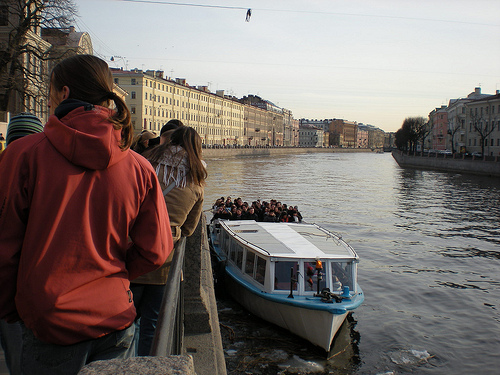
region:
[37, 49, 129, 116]
a person's head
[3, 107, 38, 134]
a person's head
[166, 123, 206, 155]
a person's head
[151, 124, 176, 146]
a person's head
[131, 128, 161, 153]
a person's head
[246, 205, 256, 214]
a person's head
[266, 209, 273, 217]
a person's head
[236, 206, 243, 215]
a person's head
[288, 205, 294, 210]
a person's head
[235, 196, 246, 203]
a person's head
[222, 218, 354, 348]
A blue and white tour boat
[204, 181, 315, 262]
sightseers ride on rear section of a boat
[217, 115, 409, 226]
a canal or river runs through the city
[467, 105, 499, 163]
a tree with no leaves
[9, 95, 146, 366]
something is pushing out against the rear of a jacket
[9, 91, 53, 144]
a green striped knitted cap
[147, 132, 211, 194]
a girl wears a fringed scarf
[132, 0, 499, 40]
an overhead cable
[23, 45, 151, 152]
a brown pony tail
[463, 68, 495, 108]
a chimney on a distant building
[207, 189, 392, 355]
a small tour boat on a canal filled with passengers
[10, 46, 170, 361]
a girl in a red hoodie and a pony tail waiting on the pier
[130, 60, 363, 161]
a long row of buildings along the canal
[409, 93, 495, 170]
several buildings and trees on the opposite side of the canal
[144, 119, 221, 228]
a girl wearing a white shawl looks over at the boat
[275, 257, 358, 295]
three front windows on the tour boat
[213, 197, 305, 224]
several people crowded together on the back of the tour boat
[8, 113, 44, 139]
a striped stocking cap someone is wearing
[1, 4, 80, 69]
a tree with bare branches next to the water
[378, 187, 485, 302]
the dark water appears slightly wavy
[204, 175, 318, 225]
people ridding the ferry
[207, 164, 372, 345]
white and blue ferry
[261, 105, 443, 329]
river in the middle of the buildings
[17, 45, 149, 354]
lady in pony tail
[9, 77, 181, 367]
lady wearing maroon hoodie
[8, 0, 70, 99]
trees without leaves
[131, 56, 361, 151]
old building beside the river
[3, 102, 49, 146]
black and green bonnet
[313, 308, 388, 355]
boat shadow in the river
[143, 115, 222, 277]
lady standing on the side wearing brown jacket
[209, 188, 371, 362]
Blue and white boat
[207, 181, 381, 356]
People on blue and white boat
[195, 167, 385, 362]
Blue and white boat in the water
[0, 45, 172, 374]
Girl in red hoodie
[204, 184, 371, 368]
blue and white boat with tourists on it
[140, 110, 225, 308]
girl with long brown hair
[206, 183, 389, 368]
blue and white boat with windows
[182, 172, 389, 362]
blue and white boat anchored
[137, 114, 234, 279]
girl with long brown hair leaning over railing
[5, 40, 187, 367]
girl with hair in ponytail